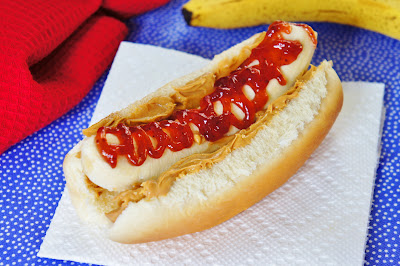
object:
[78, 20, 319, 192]
banana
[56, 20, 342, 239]
hotdog sandwich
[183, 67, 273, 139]
jelly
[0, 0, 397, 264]
table cloth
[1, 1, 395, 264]
stars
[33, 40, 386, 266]
napkin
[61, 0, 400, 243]
food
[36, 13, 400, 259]
curb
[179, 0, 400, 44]
banana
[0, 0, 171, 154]
towel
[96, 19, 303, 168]
peanut butter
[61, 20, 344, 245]
bun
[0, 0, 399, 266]
table